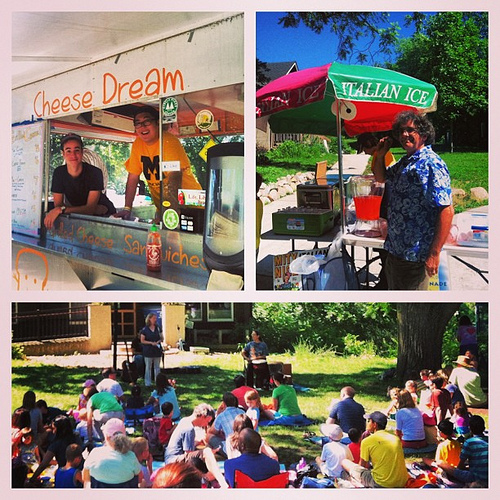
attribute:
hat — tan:
[144, 309, 156, 323]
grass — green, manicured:
[256, 145, 500, 208]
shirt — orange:
[121, 127, 204, 201]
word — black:
[136, 152, 169, 185]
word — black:
[145, 178, 160, 186]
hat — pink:
[100, 417, 125, 446]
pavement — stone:
[253, 229, 489, 292]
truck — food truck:
[16, 10, 246, 294]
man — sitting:
[224, 429, 280, 485]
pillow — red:
[402, 472, 436, 490]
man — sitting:
[359, 408, 409, 488]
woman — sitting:
[273, 373, 299, 418]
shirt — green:
[269, 382, 298, 416]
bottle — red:
[147, 225, 166, 280]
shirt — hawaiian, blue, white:
[378, 143, 450, 264]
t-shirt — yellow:
[359, 428, 413, 491]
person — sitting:
[147, 374, 183, 422]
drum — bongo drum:
[253, 356, 268, 381]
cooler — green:
[271, 202, 336, 236]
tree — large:
[366, 14, 495, 151]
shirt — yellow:
[367, 428, 407, 478]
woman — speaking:
[134, 310, 174, 383]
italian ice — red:
[348, 194, 382, 220]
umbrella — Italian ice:
[268, 57, 450, 135]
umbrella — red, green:
[263, 56, 457, 146]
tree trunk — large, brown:
[393, 299, 461, 371]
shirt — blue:
[388, 141, 455, 253]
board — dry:
[12, 118, 44, 245]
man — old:
[369, 106, 464, 295]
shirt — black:
[47, 158, 109, 215]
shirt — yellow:
[125, 134, 198, 213]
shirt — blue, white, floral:
[380, 147, 456, 270]